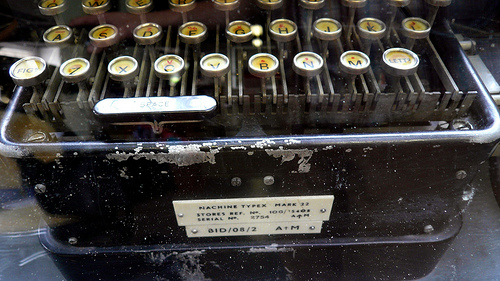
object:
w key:
[80, 0, 109, 15]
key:
[108, 56, 140, 82]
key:
[59, 57, 92, 83]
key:
[380, 47, 420, 77]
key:
[292, 51, 324, 77]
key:
[200, 53, 232, 78]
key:
[89, 23, 121, 47]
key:
[153, 54, 186, 80]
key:
[338, 50, 371, 75]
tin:
[380, 47, 420, 77]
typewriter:
[0, 0, 500, 281]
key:
[8, 56, 48, 87]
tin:
[9, 56, 49, 87]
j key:
[312, 17, 343, 40]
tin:
[224, 20, 254, 43]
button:
[59, 57, 90, 83]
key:
[43, 24, 73, 49]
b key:
[247, 53, 279, 78]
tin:
[0, 74, 500, 281]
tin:
[59, 57, 93, 84]